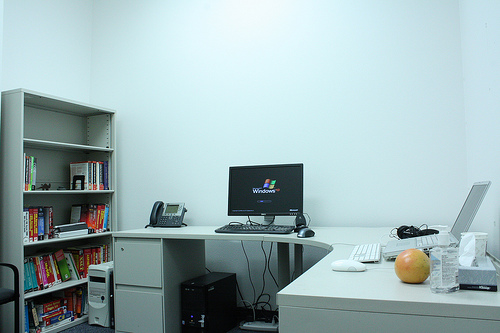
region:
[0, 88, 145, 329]
five shelf white bookcase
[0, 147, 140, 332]
several assorted size books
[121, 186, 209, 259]
large black desk telephone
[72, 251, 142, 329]
white computer hardrive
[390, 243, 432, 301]
very large yellow grapefruit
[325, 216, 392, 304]
white keyboard for computer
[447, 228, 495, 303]
box of white tissues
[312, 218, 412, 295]
white mouse for computer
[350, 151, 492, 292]
large screen laptop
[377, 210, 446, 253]
black electric cords for the computer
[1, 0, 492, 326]
a neatly arranged office space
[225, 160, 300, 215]
the monitor of a computer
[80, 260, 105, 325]
a white computer tower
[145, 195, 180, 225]
a fax machine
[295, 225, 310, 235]
a black computer mouse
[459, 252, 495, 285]
a box of face tissues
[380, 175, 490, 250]
a laptop computer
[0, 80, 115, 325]
a bookshelf with books on it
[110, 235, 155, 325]
filing cabinets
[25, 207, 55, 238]
books on a shelf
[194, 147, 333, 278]
a desktop computer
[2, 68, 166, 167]
an empty shelf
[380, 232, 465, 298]
a yellow apple on the desk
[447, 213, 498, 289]
a box of facial tissue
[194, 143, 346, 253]
the windows logo on a computer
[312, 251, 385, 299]
a white computer mouse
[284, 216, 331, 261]
a black and silver computer mouse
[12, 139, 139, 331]
four shelves of books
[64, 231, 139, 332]
a white computer tower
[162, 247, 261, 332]
a black computer tower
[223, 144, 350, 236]
black monitor sitting on desk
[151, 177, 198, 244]
gray telephone is on desk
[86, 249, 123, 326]
white computer tower on floor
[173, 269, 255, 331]
black computer tower on floor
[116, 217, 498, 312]
large curved white desk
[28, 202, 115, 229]
colorful books lined up on shelf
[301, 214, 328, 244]
gray mouse near computer monitor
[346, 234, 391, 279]
white keyboard on desk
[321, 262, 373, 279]
white mouse by keyboard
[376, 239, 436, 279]
round orange ball on desk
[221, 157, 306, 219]
a small flat screen monitor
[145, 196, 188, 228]
a small business phone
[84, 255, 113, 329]
a desktop computer on the floor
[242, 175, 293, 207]
the Windows is booting screen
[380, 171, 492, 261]
a laptop computer on a desktop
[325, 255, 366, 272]
a mouse for the laptop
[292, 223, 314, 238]
a mouse for the desktop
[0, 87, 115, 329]
a five shelved book case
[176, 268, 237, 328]
a black bag under the desk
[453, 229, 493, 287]
a box of facial tissues